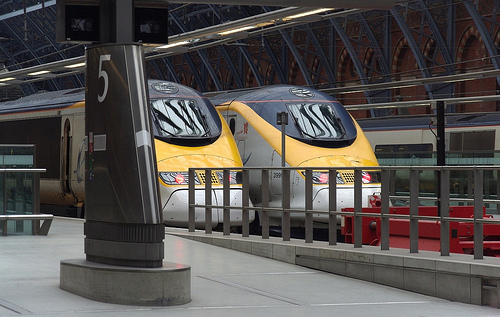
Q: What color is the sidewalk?
A: Gray.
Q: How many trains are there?
A: Two.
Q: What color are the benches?
A: Red.